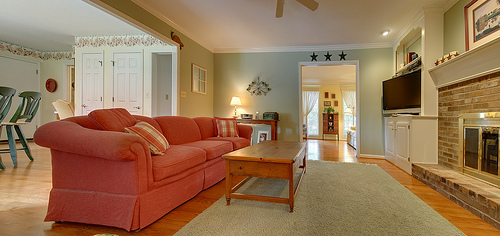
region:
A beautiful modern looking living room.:
[0, 0, 497, 232]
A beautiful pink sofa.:
[30, 105, 250, 230]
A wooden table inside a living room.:
[220, 138, 306, 213]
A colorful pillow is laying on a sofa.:
[123, 118, 168, 154]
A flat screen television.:
[380, 67, 421, 114]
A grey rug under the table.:
[172, 157, 467, 233]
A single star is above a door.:
[335, 48, 347, 60]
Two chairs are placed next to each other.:
[0, 86, 43, 166]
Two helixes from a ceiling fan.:
[272, 0, 319, 19]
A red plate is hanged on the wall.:
[43, 76, 57, 93]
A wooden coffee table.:
[221, 136, 308, 211]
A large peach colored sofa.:
[34, 105, 254, 231]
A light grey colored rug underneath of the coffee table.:
[166, 159, 466, 234]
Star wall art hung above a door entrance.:
[305, 50, 349, 62]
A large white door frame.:
[296, 60, 361, 159]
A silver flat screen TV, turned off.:
[379, 68, 425, 113]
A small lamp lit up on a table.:
[229, 92, 242, 119]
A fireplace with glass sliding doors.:
[457, 114, 498, 183]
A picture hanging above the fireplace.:
[463, 0, 498, 52]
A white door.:
[112, 52, 142, 110]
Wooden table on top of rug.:
[216, 129, 317, 219]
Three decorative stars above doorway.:
[300, 45, 360, 80]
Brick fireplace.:
[433, 92, 497, 192]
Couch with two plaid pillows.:
[34, 105, 241, 230]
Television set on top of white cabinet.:
[372, 70, 429, 157]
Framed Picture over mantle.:
[455, 0, 498, 84]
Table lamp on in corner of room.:
[213, 92, 253, 121]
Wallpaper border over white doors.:
[70, 29, 155, 79]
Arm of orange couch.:
[30, 122, 155, 234]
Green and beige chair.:
[0, 88, 39, 169]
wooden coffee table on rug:
[221, 138, 308, 211]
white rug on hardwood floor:
[170, 160, 470, 235]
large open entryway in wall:
[296, 60, 360, 160]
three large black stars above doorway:
[306, 52, 348, 61]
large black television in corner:
[381, 68, 422, 111]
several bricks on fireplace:
[411, 73, 498, 229]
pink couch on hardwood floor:
[31, 106, 253, 232]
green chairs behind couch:
[0, 81, 42, 171]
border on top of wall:
[0, 30, 172, 62]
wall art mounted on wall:
[244, 75, 271, 97]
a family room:
[28, 48, 499, 235]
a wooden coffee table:
[219, 130, 320, 219]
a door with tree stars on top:
[288, 47, 368, 158]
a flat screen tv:
[380, 68, 428, 122]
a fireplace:
[451, 101, 496, 176]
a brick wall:
[438, 111, 454, 148]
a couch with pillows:
[25, 102, 209, 234]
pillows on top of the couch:
[85, 100, 172, 152]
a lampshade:
[227, 91, 242, 119]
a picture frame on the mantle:
[456, 1, 498, 48]